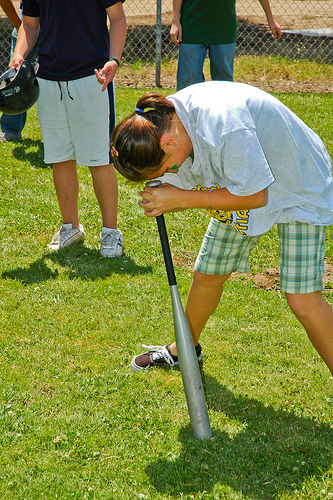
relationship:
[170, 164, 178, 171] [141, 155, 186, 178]
paint on face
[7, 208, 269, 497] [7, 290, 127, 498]
field in grass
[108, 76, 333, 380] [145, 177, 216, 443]
woman holding bat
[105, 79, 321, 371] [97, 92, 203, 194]
woman with head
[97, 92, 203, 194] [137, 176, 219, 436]
head on bat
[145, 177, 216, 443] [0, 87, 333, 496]
bat on ground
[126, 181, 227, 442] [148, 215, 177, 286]
bat with handle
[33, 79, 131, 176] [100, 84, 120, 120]
white shorts with navy stripe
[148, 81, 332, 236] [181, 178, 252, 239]
tee shirt with writing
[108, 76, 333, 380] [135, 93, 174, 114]
woman with ponytail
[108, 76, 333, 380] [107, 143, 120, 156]
woman wearing a barrette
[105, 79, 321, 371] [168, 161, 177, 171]
woman with paint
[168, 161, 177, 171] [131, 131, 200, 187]
paint on face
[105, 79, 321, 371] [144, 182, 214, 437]
woman leaning on a baseball bat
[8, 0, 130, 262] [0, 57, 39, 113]
man holding baseball helmet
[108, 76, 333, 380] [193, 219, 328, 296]
woman wearing shorts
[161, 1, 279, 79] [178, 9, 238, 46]
man wearing shirt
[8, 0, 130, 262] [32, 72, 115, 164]
man wearing shorts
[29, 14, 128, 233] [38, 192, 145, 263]
man wearing shoes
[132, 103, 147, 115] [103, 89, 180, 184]
blue band in hair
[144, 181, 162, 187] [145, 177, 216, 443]
silver handle on bat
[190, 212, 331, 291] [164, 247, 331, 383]
shorts on legs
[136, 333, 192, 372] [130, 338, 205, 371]
shoe laces on shoe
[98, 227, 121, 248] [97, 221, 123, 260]
laces on shoe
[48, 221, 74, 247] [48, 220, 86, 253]
laces on shoe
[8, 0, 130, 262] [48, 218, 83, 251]
man wearing shoe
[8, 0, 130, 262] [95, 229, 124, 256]
man wearing shoe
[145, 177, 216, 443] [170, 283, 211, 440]
bat covering metal